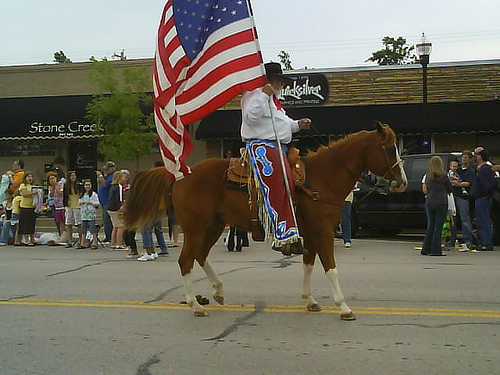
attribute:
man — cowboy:
[233, 55, 287, 227]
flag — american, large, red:
[162, 5, 253, 115]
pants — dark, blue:
[239, 152, 296, 227]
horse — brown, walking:
[147, 160, 346, 257]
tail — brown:
[112, 167, 175, 225]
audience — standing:
[2, 170, 96, 234]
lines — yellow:
[74, 283, 145, 318]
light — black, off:
[406, 69, 433, 93]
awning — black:
[0, 108, 22, 141]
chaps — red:
[261, 181, 306, 243]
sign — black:
[295, 62, 330, 110]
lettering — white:
[290, 84, 313, 97]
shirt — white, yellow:
[254, 93, 267, 111]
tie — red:
[270, 91, 285, 109]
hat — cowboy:
[263, 61, 296, 83]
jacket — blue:
[98, 183, 109, 198]